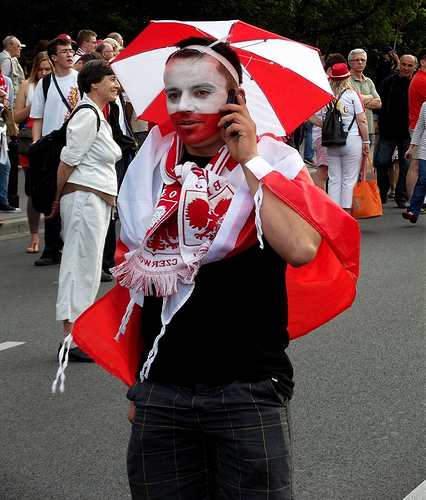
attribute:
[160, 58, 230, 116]
paint — white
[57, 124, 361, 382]
flag — red and white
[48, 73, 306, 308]
clothes — white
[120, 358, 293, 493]
pants — blue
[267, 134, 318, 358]
her bag — black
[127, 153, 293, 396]
shirt — black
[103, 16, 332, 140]
umbrella — mini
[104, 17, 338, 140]
sunhat — red, white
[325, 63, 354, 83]
hat — red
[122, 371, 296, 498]
pants — plaid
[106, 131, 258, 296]
scarf — red and white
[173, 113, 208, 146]
paint — red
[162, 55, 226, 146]
face — painted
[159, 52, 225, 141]
face — painted white and red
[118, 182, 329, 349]
shirt — black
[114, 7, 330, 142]
hat — red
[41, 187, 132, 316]
pants — white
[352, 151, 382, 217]
bag — orange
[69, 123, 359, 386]
cape — red, white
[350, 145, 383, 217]
bag — orange